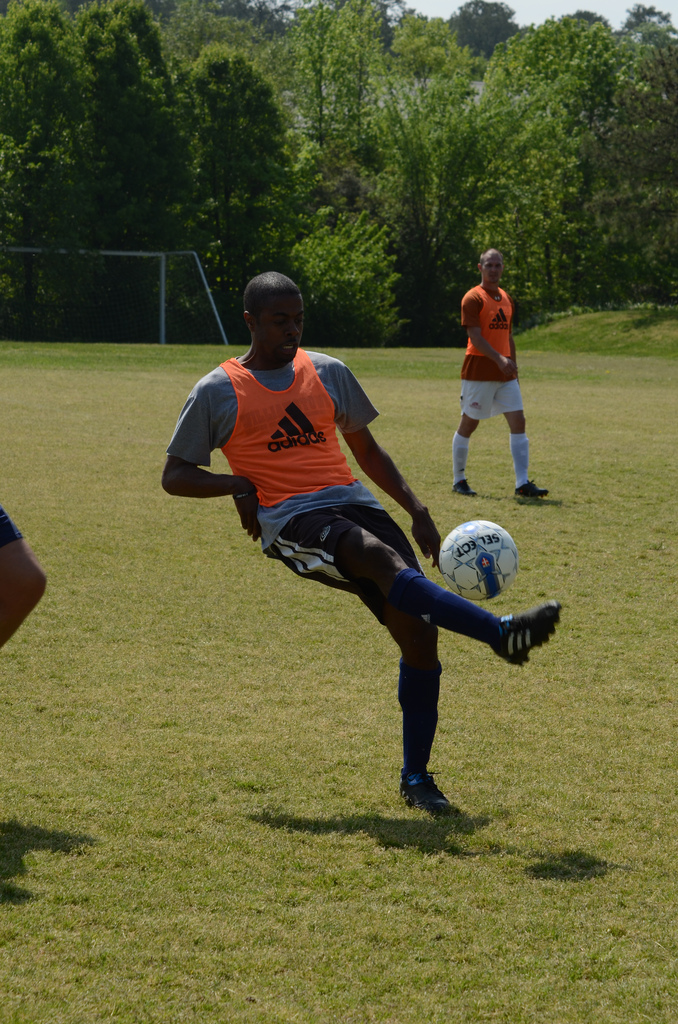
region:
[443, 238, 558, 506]
a player with a uniform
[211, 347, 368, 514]
the vest color orange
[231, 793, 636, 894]
shadow on the grass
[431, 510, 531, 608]
the ball is white and blue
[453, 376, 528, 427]
the pants are white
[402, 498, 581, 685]
ball above a leg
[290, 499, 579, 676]
a leg in the air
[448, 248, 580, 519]
a man walking with white shorts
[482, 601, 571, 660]
a black shoe with white stripes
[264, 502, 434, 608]
black shorts with white stripes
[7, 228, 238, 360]
white poles to the goal area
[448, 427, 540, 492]
white knee high socks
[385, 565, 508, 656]
blue knee high sock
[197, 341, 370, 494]
an orange Adidas shirt over a gray shirt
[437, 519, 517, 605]
A white and black soccer ball.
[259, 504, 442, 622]
A pair of black shorts with white stripes.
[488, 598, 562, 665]
A pair of black and white shoes.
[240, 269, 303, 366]
A man with a shaved head.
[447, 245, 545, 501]
A man wearing soccer gear.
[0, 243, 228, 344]
A soccer goal nestled up against a forest.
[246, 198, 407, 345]
A green tree filled with lots of leaves.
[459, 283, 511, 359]
An orange wife beater shirt.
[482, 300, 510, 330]
An Adidas logo on a shirt.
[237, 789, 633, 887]
shadow cast upon grass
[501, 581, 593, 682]
foot wearing a black cleat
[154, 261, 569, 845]
man kicking a soccer ball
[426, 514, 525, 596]
blue and white soccer ball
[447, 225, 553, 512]
man walking on soccer field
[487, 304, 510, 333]
black logo on orange shirt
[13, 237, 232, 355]
metal soccer goal under tree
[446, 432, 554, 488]
white socks covering hairy legs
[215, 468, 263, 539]
hand resting on a hip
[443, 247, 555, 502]
The man not kicking the ball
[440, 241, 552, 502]
A person not kicking the ball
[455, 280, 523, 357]
The orange vest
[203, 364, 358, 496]
A orange vest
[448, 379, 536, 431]
The short white pants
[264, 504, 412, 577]
A short black and white pant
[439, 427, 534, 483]
The high white socks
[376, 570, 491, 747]
The high blue socks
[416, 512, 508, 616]
blue and white soccer ball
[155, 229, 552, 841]
man kicking soccer ball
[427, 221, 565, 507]
man walking on field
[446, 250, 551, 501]
Man in bright orange vest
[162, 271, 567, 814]
Man in orange playing soccer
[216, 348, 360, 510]
Bright orange Adidas vest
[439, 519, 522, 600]
Soccer ball with blue stripe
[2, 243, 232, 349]
Soccer goal under a tree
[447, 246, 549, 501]
Man in white shorts and socks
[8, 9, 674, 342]
Lush green trees behind soccer field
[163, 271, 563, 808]
Guy kicking a soccer ball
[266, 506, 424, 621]
Black soccer shorts with white stripe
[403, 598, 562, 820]
Black soccer shoes with white stripes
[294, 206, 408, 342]
A tree in the woods.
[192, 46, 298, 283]
A tree in the woods.